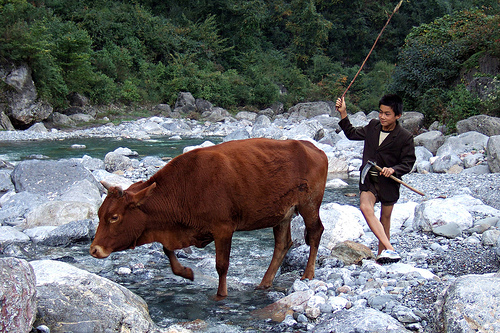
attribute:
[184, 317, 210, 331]
pebble — tan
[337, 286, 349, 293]
pebble — tan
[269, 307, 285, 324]
pebble — tan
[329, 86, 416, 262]
boy — smiling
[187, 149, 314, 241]
fur — brown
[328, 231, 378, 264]
rock — dryish, brown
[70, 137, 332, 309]
cow — brown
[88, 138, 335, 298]
cow — brown 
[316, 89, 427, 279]
boy — carrying